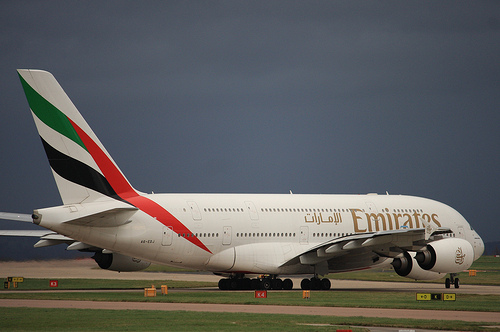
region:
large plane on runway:
[14, 53, 473, 294]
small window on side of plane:
[202, 204, 205, 214]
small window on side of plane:
[213, 229, 220, 240]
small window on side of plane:
[234, 230, 241, 237]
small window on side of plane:
[310, 232, 315, 239]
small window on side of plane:
[317, 230, 321, 240]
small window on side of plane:
[264, 204, 269, 211]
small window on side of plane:
[240, 205, 247, 214]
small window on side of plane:
[183, 232, 188, 239]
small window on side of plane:
[214, 232, 218, 239]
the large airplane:
[12, 52, 494, 294]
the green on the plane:
[30, 103, 63, 118]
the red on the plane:
[102, 164, 127, 186]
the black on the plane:
[57, 151, 87, 174]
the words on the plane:
[297, 198, 451, 245]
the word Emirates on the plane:
[347, 202, 439, 240]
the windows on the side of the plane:
[154, 197, 446, 244]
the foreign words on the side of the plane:
[302, 210, 342, 228]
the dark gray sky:
[126, 43, 424, 180]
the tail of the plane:
[14, 60, 127, 196]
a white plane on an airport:
[1, 59, 493, 306]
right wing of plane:
[271, 208, 430, 288]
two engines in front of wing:
[386, 236, 478, 286]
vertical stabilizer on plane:
[9, 59, 148, 201]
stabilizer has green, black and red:
[10, 61, 147, 203]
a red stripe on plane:
[59, 108, 220, 262]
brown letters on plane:
[294, 196, 450, 236]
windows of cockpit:
[445, 199, 488, 259]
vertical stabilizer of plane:
[53, 199, 147, 239]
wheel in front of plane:
[436, 271, 465, 293]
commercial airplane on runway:
[1, 65, 479, 295]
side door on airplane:
[216, 222, 235, 246]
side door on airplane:
[184, 198, 206, 224]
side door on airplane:
[160, 220, 173, 248]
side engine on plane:
[412, 237, 465, 275]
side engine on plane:
[385, 256, 433, 281]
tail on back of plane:
[13, 52, 132, 205]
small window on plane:
[255, 203, 267, 215]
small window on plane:
[269, 204, 276, 212]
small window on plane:
[285, 202, 290, 211]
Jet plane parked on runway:
[28, 176, 475, 329]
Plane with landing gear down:
[202, 264, 466, 306]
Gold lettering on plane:
[300, 205, 449, 232]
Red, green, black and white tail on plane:
[32, 97, 153, 208]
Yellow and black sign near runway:
[410, 287, 460, 302]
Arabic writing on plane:
[301, 209, 349, 233]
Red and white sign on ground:
[251, 289, 269, 306]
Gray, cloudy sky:
[136, 27, 408, 154]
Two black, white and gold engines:
[384, 232, 477, 293]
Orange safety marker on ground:
[463, 265, 489, 280]